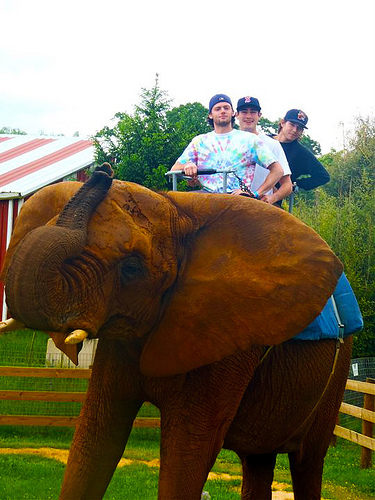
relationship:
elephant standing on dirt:
[3, 174, 364, 499] [4, 444, 373, 499]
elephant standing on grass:
[3, 174, 364, 499] [0, 328, 374, 497]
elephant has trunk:
[3, 174, 364, 499] [7, 162, 116, 338]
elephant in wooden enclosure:
[3, 174, 364, 499] [19, 108, 356, 285]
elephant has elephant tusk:
[3, 174, 364, 499] [64, 329, 88, 344]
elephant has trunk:
[10, 181, 305, 329] [19, 183, 149, 298]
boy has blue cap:
[168, 93, 283, 209] [208, 91, 234, 114]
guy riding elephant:
[166, 91, 282, 197] [3, 174, 364, 499]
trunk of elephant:
[7, 162, 116, 338] [3, 174, 364, 499]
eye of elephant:
[121, 257, 143, 280] [3, 174, 364, 499]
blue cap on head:
[208, 91, 234, 114] [279, 109, 309, 141]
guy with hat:
[166, 91, 282, 197] [282, 109, 309, 132]